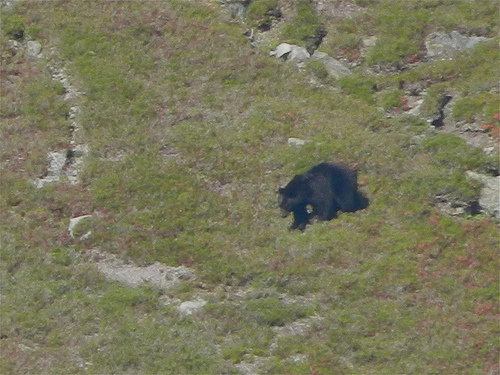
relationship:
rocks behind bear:
[268, 37, 358, 92] [274, 161, 370, 233]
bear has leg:
[274, 161, 370, 233] [295, 205, 310, 232]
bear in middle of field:
[274, 161, 370, 233] [55, 105, 282, 337]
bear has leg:
[274, 161, 370, 233] [283, 206, 307, 228]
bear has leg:
[274, 161, 370, 233] [302, 201, 327, 217]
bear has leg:
[274, 161, 370, 233] [320, 187, 343, 226]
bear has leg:
[274, 161, 370, 233] [342, 190, 372, 207]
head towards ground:
[279, 183, 304, 222] [2, 0, 499, 373]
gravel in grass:
[115, 266, 190, 286] [135, 183, 259, 262]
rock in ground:
[50, 215, 110, 265] [68, 164, 146, 240]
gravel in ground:
[31, 135, 99, 198] [68, 164, 146, 240]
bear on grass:
[251, 152, 376, 242] [5, 1, 498, 365]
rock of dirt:
[97, 235, 192, 308] [86, 245, 196, 295]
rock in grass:
[54, 188, 123, 336] [100, 128, 280, 275]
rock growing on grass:
[53, 218, 109, 258] [5, 1, 498, 365]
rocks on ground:
[239, 0, 360, 81] [19, 158, 122, 253]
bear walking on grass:
[274, 161, 370, 233] [274, 224, 359, 314]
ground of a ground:
[0, 0, 500, 375] [150, 154, 227, 235]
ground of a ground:
[0, 0, 500, 375] [83, 233, 245, 343]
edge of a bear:
[290, 207, 367, 231] [274, 161, 370, 233]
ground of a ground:
[0, 0, 500, 375] [322, 240, 487, 335]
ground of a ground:
[0, 0, 500, 375] [405, 145, 445, 230]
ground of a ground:
[0, 0, 500, 375] [2, 0, 499, 373]